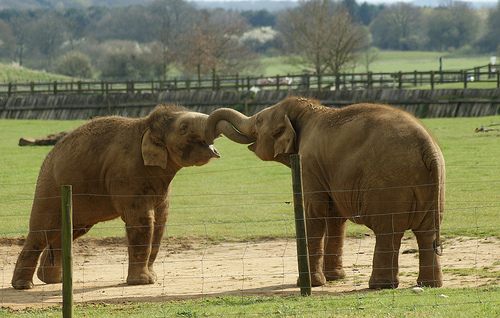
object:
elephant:
[10, 102, 258, 290]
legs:
[35, 223, 94, 285]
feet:
[416, 272, 443, 288]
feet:
[368, 275, 400, 289]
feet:
[296, 271, 326, 287]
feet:
[321, 267, 347, 281]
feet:
[125, 271, 156, 286]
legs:
[412, 177, 445, 288]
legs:
[367, 183, 413, 289]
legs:
[323, 196, 350, 280]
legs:
[295, 160, 331, 287]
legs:
[104, 165, 155, 285]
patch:
[1, 232, 500, 309]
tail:
[430, 155, 442, 256]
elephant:
[203, 94, 446, 289]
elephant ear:
[141, 126, 169, 170]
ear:
[272, 110, 298, 158]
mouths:
[201, 135, 224, 159]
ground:
[0, 114, 500, 318]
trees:
[317, 17, 374, 89]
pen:
[0, 70, 500, 318]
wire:
[0, 228, 61, 235]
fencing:
[0, 152, 500, 318]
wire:
[299, 161, 500, 165]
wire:
[72, 192, 294, 197]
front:
[1, 150, 500, 317]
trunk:
[201, 115, 255, 144]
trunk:
[203, 106, 250, 145]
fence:
[0, 69, 500, 121]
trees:
[429, 0, 485, 50]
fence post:
[59, 184, 74, 318]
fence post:
[287, 153, 313, 298]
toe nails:
[16, 284, 23, 289]